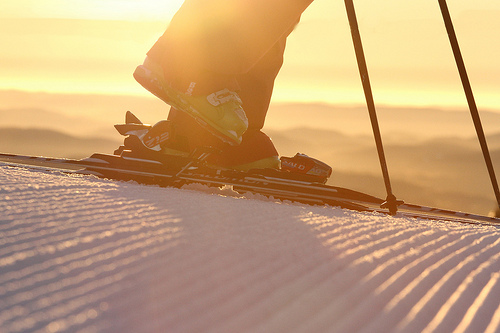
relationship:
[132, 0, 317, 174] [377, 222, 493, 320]
skier prepares to descend down mountain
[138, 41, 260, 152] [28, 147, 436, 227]
foot off ski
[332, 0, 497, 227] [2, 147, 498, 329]
ski poles on snow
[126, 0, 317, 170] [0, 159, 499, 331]
skier on mountain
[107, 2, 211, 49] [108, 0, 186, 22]
glare from glare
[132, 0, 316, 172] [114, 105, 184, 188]
person into ski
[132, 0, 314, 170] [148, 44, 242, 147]
person has foot